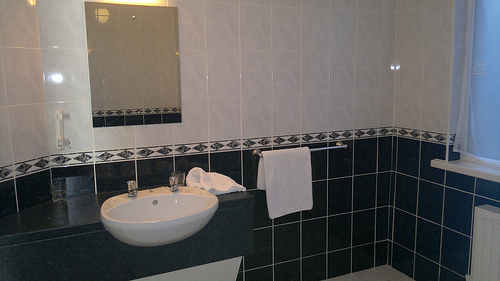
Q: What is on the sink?
A: Chrome taps.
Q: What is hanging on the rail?
A: Folded towel.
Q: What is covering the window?
A: Curtain.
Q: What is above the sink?
A: Mirror.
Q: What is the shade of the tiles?
A: Black and white.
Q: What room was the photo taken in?
A: Bathroom.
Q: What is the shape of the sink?
A: Bowl.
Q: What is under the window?
A: Toilet.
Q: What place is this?
A: Bathroom.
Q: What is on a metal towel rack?
A: White towel.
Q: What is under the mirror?
A: White sink.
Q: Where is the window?
A: The right side of this picture.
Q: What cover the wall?
A: Tiles.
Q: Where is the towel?
A: Lying on the counter.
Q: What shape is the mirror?
A: Rectangular.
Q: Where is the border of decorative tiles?
A: On the wall.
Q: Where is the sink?
A: On the counter.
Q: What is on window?
A: White curtain.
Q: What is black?
A: Tiles.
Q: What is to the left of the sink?
A: Handle.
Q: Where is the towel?
A: Right of the sink.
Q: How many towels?
A: Two.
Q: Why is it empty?
A: Not in use.